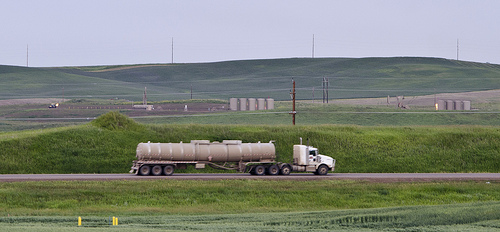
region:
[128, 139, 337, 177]
Large tank being pulled by semi truck.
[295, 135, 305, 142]
Exhaust pipe on semi truck.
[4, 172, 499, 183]
A straight stretch of highway.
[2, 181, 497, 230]
Green grass along the side of the road.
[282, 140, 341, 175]
White semi truck.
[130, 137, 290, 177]
Large tan tanker trailer.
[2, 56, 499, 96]
Green hills in the distance.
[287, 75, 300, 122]
A brown wooden utility pole.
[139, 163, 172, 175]
Rear wheels of the tanker trailer.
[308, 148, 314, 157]
Passenger window on the semi truck.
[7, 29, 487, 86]
grass covered refuse hill with vent pipes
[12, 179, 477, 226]
green grassy area next to road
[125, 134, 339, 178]
tractor trailer rolling down the road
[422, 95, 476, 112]
gray structures in a field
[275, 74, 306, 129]
brown utility pole in a field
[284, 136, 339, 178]
white tractor of an over the road truck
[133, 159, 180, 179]
rear wheels of a trailer tanker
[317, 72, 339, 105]
utility poles in a field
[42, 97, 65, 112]
heavy equipment working in a dirt area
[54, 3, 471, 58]
light blue sky over grassy hill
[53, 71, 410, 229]
an 18 wheeler driving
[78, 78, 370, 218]
an 18 wheeler driving on the road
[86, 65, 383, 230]
an 18 wheeler driving on road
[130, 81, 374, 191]
an 18 wheeler driving on street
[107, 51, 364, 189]
an 18 wheeler with a cab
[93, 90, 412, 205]
18 wheeler with white cab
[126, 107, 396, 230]
a white cab driving down the road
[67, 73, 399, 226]
grass next to the road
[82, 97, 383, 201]
18 wheeler driving next to grass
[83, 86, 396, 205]
white 18 wheeler driving next to grass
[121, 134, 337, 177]
a large oil truck driving down the road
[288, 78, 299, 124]
a wooden telephone pole in the field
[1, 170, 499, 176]
a narrow country road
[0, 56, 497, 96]
rolling hills of green grass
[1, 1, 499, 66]
a hazy blue sky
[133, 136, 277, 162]
an oil tank on the truck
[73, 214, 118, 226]
small yellow markers in the ground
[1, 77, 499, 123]
telephone wires spanning over the field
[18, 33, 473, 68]
four more telephone poles in the distance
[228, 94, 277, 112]
five metal cylindrical barrels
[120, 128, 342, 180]
A large tanker truck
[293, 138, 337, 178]
A white cab of tanker truck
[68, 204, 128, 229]
Three yellow post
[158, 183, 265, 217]
A field of green grass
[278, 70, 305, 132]
A dark brown post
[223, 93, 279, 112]
Five metal round containers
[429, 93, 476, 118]
Four round containers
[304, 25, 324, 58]
Tall poles on a hill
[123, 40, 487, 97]
A large hilltop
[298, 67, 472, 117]
Electric wires strung from poles